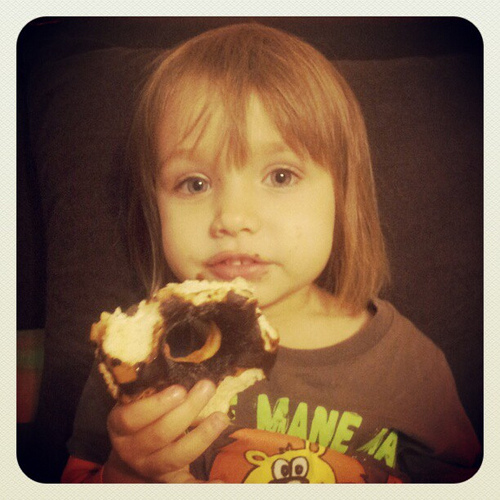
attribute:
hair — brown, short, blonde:
[116, 21, 392, 319]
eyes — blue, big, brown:
[169, 171, 212, 198]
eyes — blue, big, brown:
[261, 164, 303, 191]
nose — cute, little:
[207, 177, 263, 238]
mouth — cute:
[202, 245, 275, 279]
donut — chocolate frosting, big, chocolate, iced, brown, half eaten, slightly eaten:
[87, 273, 280, 437]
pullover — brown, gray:
[75, 279, 481, 493]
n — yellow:
[310, 402, 339, 457]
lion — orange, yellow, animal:
[209, 424, 371, 486]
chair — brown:
[29, 46, 483, 482]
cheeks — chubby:
[273, 216, 335, 276]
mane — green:
[252, 390, 362, 458]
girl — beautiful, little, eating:
[64, 25, 480, 499]